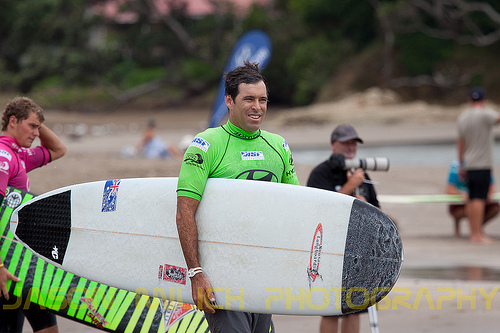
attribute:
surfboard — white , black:
[10, 178, 404, 316]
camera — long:
[332, 152, 390, 200]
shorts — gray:
[195, 307, 273, 333]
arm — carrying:
[176, 133, 215, 313]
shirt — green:
[176, 122, 303, 316]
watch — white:
[187, 267, 202, 278]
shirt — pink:
[2, 135, 53, 200]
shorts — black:
[2, 287, 57, 332]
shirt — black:
[308, 154, 380, 211]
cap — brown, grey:
[330, 124, 362, 145]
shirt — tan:
[460, 105, 498, 170]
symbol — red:
[157, 263, 187, 286]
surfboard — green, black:
[2, 189, 212, 332]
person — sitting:
[134, 117, 175, 157]